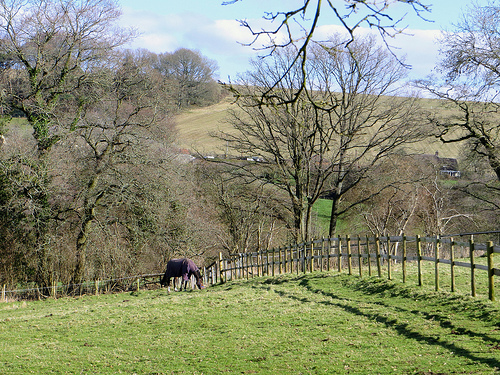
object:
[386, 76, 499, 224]
trees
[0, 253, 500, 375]
green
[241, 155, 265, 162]
buildings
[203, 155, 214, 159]
buildings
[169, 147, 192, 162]
buildings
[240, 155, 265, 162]
buildings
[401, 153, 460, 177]
buildings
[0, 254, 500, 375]
grass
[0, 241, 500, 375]
pasture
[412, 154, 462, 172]
scissors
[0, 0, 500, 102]
sky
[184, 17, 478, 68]
clouds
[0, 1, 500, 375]
field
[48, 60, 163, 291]
tree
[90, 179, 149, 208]
branches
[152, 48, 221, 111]
trees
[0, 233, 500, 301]
fence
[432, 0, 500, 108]
tree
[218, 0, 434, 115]
tree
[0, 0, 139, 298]
tree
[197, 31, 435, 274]
tree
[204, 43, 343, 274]
trees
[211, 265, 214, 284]
slat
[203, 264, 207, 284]
slat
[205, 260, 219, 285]
gate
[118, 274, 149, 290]
post fence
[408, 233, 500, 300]
post fence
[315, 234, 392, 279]
post fence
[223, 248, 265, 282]
post fence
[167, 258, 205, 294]
blanket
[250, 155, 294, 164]
roof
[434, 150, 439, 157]
chimney